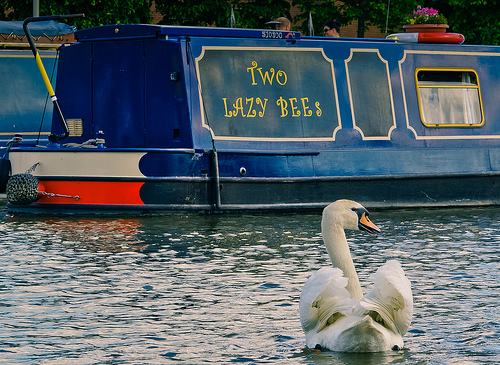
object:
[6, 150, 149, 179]
stripe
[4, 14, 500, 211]
boat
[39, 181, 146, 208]
stripe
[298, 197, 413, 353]
swan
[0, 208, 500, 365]
water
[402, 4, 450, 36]
plant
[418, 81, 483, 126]
curtain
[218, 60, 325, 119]
name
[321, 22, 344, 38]
man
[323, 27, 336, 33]
sunglasses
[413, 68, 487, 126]
window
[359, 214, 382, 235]
beak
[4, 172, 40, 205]
rope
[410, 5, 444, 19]
flowers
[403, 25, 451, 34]
pot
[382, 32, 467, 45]
life preserver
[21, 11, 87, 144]
pole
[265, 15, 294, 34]
man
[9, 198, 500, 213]
bottom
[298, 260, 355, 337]
feathers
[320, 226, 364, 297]
neck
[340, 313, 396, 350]
back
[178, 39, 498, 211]
side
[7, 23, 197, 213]
back